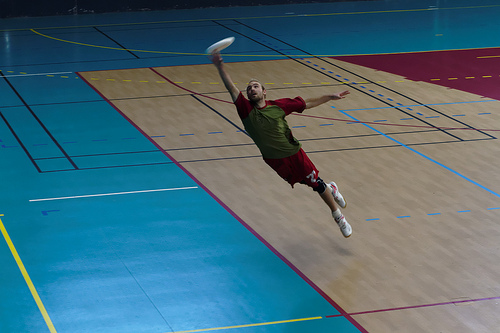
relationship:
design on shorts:
[306, 171, 318, 184] [265, 148, 319, 186]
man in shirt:
[209, 49, 354, 238] [233, 90, 305, 160]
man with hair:
[209, 49, 354, 238] [248, 80, 266, 90]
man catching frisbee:
[209, 49, 354, 238] [206, 35, 234, 54]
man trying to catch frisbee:
[209, 49, 354, 238] [206, 35, 234, 54]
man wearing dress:
[209, 49, 354, 238] [232, 90, 319, 189]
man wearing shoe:
[209, 49, 354, 238] [327, 179, 348, 208]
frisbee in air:
[206, 35, 234, 54] [164, 12, 262, 54]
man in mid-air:
[209, 49, 354, 238] [169, 46, 402, 269]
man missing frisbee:
[209, 49, 354, 238] [206, 35, 234, 54]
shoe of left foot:
[332, 210, 352, 236] [335, 212, 354, 239]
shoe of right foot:
[328, 182, 348, 208] [327, 181, 349, 207]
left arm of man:
[287, 93, 331, 113] [209, 49, 354, 238]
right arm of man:
[216, 67, 240, 112] [209, 49, 354, 238]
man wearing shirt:
[209, 49, 354, 238] [233, 90, 305, 160]